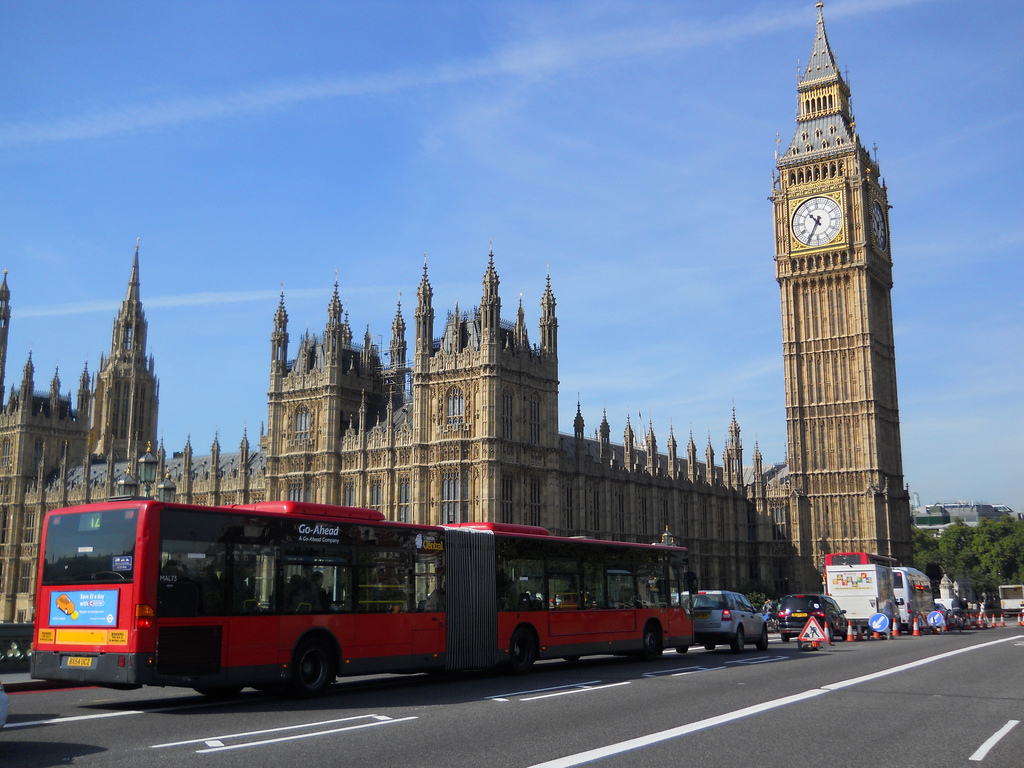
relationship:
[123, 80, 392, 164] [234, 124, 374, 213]
clouds in sky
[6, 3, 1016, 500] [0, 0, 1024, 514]
clouds in blue sky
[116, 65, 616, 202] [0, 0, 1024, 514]
clouds in blue sky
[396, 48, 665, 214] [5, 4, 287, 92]
white clouds in blue sky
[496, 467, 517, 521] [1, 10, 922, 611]
window on building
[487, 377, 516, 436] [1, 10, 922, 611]
window on building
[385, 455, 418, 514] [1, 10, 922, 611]
window on building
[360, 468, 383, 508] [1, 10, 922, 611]
window on building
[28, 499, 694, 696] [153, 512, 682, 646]
bus with window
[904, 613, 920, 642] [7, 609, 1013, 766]
pylon on road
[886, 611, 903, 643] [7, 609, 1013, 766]
pylon on road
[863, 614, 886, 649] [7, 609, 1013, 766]
pylon on road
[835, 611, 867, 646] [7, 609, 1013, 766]
pylon on road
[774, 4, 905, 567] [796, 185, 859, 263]
big ben located above clock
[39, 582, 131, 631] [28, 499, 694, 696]
advertising rear of bus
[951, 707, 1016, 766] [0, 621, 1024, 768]
line in road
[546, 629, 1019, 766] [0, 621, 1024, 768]
line in road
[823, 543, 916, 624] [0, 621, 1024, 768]
truck parked in road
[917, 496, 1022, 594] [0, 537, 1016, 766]
tree down street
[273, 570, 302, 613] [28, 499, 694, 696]
passenger on bus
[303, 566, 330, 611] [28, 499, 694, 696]
passenger on bus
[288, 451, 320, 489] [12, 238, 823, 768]
window on building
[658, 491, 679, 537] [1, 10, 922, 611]
window on building